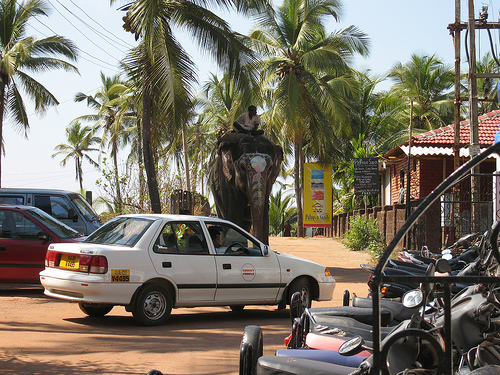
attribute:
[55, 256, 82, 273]
plate — yellow license 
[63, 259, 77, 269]
text — black 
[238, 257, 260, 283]
symbol — side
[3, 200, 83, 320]
car — red , side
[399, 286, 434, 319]
mirror — rearview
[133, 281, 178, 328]
tire — back right  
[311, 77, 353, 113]
leaves — Green 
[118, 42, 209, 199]
tree — palm 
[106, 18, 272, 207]
tree — palm 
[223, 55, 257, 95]
leaves — Green 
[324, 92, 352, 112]
leaves — Green 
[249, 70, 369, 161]
tree — palm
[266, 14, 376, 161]
tree — palm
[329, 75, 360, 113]
leaves — Green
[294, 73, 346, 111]
leaves — Green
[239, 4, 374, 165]
tree — palm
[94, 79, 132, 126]
leaves — green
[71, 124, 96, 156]
leaves — green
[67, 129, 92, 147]
leaves — green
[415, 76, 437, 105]
leaves — green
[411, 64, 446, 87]
leaves — green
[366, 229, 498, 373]
bike — parked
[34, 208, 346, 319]
car — white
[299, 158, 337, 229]
sign — yellow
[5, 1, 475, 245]
palm trees — tall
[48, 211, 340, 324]
car — white 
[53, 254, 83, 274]
license plate — yellow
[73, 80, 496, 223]
palm trees — pictured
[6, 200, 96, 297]
car — parked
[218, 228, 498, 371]
motorbikes — parked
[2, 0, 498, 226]
sky — daytime, light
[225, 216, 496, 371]
motorbikes — parked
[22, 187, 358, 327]
car — white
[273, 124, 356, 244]
banner — yellow, vertical , hanging 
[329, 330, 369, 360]
mirror — sideview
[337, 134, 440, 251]
wall — in front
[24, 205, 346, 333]
car — white , small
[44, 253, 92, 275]
license plate — yellow, black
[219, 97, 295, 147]
man — riding